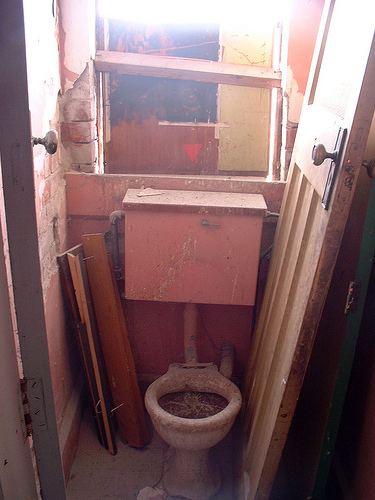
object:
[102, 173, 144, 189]
paint peeling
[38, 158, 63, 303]
paint peeling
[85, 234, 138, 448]
panels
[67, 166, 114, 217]
paint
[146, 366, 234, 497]
toilet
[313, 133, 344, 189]
handle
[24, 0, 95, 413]
peeling paint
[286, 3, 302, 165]
peeling paint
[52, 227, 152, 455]
wood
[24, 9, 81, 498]
brick wall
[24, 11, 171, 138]
paper peeling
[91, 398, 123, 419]
mails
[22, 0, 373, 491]
wall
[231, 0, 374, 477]
door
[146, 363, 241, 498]
toilet bowl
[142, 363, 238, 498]
sign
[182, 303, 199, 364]
pipe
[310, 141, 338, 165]
door knob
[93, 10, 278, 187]
window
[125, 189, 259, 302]
tank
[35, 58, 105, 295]
exposed brick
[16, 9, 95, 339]
wall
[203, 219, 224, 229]
handle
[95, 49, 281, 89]
framing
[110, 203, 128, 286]
pipe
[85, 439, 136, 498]
floor